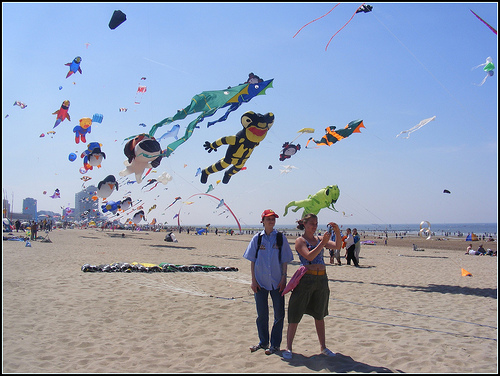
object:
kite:
[81, 261, 240, 272]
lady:
[282, 211, 342, 360]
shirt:
[297, 236, 325, 265]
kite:
[302, 119, 363, 150]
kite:
[89, 175, 118, 203]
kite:
[51, 99, 72, 129]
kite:
[117, 135, 163, 184]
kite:
[202, 111, 274, 185]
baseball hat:
[260, 209, 279, 221]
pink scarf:
[281, 265, 306, 297]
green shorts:
[286, 271, 328, 324]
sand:
[0, 227, 499, 376]